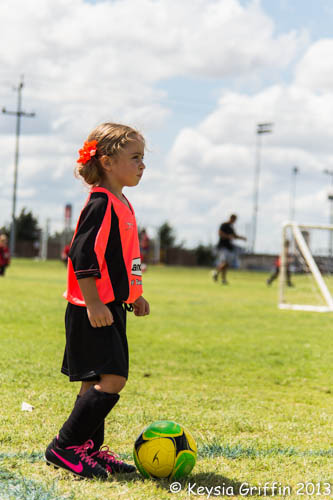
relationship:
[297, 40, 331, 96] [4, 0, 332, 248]
cloud in sky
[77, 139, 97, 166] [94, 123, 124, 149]
flower in hair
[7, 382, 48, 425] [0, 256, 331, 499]
trash on field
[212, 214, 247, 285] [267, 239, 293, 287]
adult male teaching a person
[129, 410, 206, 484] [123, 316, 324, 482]
ball on field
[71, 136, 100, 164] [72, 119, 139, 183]
bow tie in hair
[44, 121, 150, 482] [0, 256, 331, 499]
girl on field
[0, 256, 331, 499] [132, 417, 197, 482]
field with ball